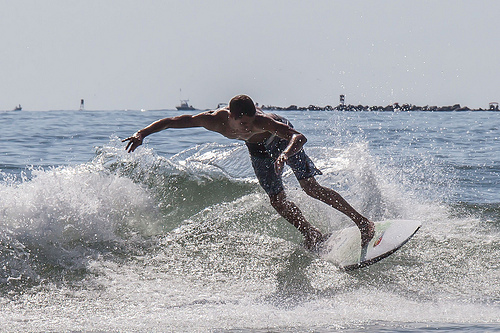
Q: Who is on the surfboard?
A: Man in blue swim trunks.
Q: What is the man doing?
A: Surfing.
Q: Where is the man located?
A: Large body of water.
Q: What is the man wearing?
A: Blue swim trunks.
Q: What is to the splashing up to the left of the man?
A: Wave.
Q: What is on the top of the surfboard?
A: Logo.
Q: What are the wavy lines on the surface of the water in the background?
A: Ripples.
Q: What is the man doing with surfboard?
A: Riding a wave.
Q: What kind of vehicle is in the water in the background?
A: Boat.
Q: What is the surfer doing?
A: Surfing.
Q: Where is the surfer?
A: In the ocean.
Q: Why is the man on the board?
A: To surf.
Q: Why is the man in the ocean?
A: To surf.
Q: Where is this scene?
A: Ocean.